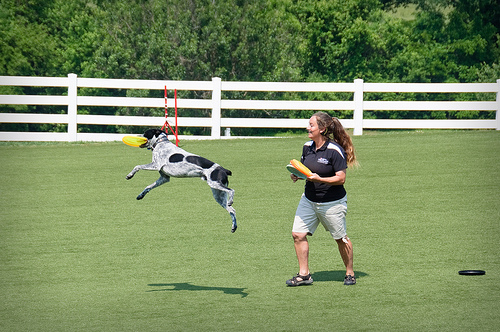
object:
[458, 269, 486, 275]
disc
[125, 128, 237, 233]
dog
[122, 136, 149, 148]
frisbee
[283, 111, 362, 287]
woman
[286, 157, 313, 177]
discs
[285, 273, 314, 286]
feet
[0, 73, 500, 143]
fence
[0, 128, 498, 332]
grass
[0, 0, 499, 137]
trees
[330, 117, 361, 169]
ponytail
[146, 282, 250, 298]
shadow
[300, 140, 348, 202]
shirt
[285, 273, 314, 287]
sandals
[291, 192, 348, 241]
shorts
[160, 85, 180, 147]
jump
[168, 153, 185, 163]
spots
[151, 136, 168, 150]
collar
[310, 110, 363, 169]
hair